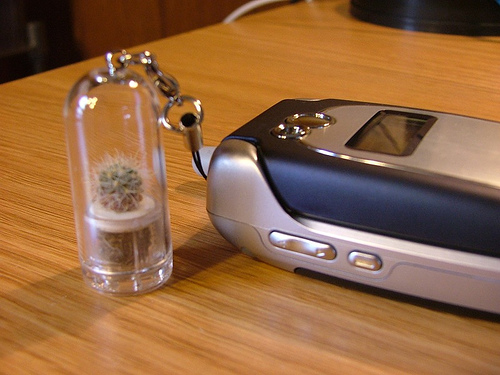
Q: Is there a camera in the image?
A: Yes, there is a camera.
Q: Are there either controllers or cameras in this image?
A: Yes, there is a camera.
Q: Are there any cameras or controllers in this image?
A: Yes, there is a camera.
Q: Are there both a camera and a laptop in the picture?
A: No, there is a camera but no laptops.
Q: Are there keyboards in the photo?
A: No, there are no keyboards.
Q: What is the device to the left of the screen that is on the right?
A: The device is a camera.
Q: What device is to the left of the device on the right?
A: The device is a camera.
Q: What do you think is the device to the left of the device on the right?
A: The device is a camera.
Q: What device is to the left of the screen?
A: The device is a camera.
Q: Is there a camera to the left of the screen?
A: Yes, there is a camera to the left of the screen.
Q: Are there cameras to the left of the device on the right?
A: Yes, there is a camera to the left of the screen.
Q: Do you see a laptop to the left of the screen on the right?
A: No, there is a camera to the left of the screen.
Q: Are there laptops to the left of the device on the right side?
A: No, there is a camera to the left of the screen.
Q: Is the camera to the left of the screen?
A: Yes, the camera is to the left of the screen.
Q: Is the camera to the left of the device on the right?
A: Yes, the camera is to the left of the screen.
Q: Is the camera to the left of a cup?
A: No, the camera is to the left of the screen.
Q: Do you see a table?
A: Yes, there is a table.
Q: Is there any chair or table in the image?
A: Yes, there is a table.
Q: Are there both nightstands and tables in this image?
A: No, there is a table but no nightstands.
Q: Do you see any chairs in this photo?
A: No, there are no chairs.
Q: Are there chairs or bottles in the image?
A: No, there are no chairs or bottles.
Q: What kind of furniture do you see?
A: The furniture is a table.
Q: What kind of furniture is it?
A: The piece of furniture is a table.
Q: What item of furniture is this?
A: This is a table.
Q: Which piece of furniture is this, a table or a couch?
A: This is a table.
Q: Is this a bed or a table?
A: This is a table.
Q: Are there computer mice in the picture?
A: No, there are no computer mice.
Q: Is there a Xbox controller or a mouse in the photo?
A: No, there are no computer mice or Xbox controllers.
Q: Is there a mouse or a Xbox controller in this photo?
A: No, there are no computer mice or Xbox controllers.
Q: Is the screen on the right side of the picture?
A: Yes, the screen is on the right of the image.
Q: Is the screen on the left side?
A: No, the screen is on the right of the image.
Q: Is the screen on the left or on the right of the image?
A: The screen is on the right of the image.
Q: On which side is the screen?
A: The screen is on the right of the image.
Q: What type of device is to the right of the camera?
A: The device is a screen.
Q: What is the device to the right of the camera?
A: The device is a screen.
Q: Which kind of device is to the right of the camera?
A: The device is a screen.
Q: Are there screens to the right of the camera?
A: Yes, there is a screen to the right of the camera.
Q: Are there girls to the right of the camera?
A: No, there is a screen to the right of the camera.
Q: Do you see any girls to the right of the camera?
A: No, there is a screen to the right of the camera.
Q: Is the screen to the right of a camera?
A: Yes, the screen is to the right of a camera.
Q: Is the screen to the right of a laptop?
A: No, the screen is to the right of a camera.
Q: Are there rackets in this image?
A: No, there are no rackets.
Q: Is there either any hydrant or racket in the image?
A: No, there are no rackets or fire hydrants.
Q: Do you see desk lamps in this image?
A: No, there are no desk lamps.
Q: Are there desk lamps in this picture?
A: No, there are no desk lamps.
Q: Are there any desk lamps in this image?
A: No, there are no desk lamps.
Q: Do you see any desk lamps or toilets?
A: No, there are no desk lamps or toilets.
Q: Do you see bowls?
A: No, there are no bowls.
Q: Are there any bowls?
A: No, there are no bowls.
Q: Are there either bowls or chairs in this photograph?
A: No, there are no bowls or chairs.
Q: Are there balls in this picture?
A: Yes, there is a ball.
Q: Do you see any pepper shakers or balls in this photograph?
A: Yes, there is a ball.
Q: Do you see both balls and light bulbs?
A: No, there is a ball but no light bulbs.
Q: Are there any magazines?
A: No, there are no magazines.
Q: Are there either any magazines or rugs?
A: No, there are no magazines or rugs.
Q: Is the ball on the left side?
A: Yes, the ball is on the left of the image.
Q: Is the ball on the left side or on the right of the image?
A: The ball is on the left of the image.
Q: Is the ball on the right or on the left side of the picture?
A: The ball is on the left of the image.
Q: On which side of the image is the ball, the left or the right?
A: The ball is on the left of the image.